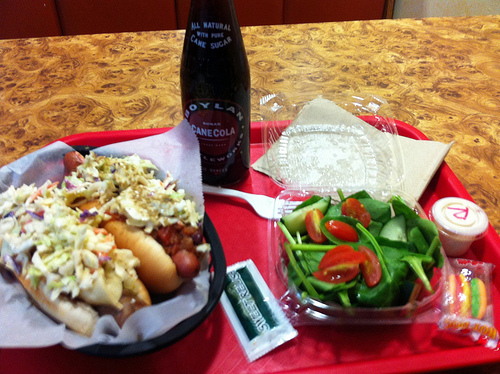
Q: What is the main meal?
A: Two hot dogs with toppings.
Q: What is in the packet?
A: Relish.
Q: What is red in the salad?
A: Tomatos.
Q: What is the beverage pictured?
A: Cane soda.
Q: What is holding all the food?
A: A red tray.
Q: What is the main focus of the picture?
A: A tray of food.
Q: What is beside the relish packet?
A: A small side salad.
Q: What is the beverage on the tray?
A: A bottle of soda.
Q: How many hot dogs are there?
A: Two.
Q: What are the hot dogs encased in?
A: Buns.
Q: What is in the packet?
A: Dressing.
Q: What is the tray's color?
A: Red.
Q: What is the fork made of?
A: Plastic.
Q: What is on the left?
A: Hot dog.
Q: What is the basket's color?
A: Black.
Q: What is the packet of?
A: Sweetener.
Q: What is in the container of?
A: Salad.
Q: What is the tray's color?
A: Red.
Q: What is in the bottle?
A: Cola.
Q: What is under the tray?
A: Table.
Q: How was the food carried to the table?
A: On a red tray.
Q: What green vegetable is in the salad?
A: Spinach.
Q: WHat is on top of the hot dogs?
A: Cole slaw.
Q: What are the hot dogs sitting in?
A: A black basket.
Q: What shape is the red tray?
A: Rectangular.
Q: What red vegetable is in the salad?
A: Tomatoes.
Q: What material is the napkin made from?
A: Paper.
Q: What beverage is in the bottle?
A: Soda.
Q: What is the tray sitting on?
A: The table.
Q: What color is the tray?
A: Red.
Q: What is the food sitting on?
A: Tray.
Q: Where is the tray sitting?
A: Table.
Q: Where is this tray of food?
A: Restaurant.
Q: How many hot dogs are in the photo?
A: Two.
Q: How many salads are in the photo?
A: One.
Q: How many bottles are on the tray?
A: One.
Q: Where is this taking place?
A: At a table.